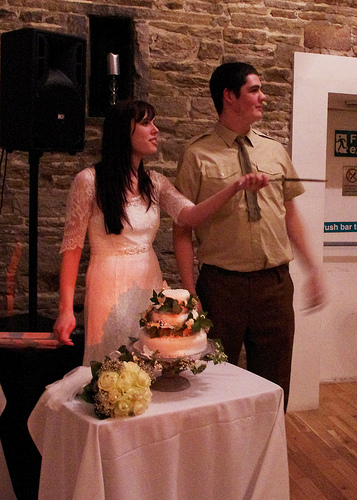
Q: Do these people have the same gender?
A: No, they are both male and female.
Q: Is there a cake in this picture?
A: Yes, there is a cake.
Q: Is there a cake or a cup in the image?
A: Yes, there is a cake.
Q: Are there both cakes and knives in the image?
A: Yes, there are both a cake and a knife.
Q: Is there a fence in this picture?
A: No, there are no fences.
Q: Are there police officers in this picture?
A: No, there are no police officers.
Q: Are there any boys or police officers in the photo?
A: No, there are no police officers or boys.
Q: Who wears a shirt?
A: The man wears a shirt.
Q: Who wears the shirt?
A: The man wears a shirt.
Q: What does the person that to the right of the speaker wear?
A: The man wears a shirt.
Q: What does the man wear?
A: The man wears a shirt.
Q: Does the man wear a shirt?
A: Yes, the man wears a shirt.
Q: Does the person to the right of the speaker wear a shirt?
A: Yes, the man wears a shirt.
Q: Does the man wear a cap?
A: No, the man wears a shirt.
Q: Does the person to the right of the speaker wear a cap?
A: No, the man wears a shirt.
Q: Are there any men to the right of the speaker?
A: Yes, there is a man to the right of the speaker.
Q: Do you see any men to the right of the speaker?
A: Yes, there is a man to the right of the speaker.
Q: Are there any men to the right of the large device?
A: Yes, there is a man to the right of the speaker.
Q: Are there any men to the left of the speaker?
A: No, the man is to the right of the speaker.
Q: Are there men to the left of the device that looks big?
A: No, the man is to the right of the speaker.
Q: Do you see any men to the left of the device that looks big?
A: No, the man is to the right of the speaker.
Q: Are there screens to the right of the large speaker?
A: No, there is a man to the right of the speaker.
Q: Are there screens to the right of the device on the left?
A: No, there is a man to the right of the speaker.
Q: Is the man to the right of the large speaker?
A: Yes, the man is to the right of the speaker.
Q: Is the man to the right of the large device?
A: Yes, the man is to the right of the speaker.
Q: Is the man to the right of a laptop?
A: No, the man is to the right of the speaker.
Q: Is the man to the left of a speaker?
A: No, the man is to the right of a speaker.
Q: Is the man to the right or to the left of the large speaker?
A: The man is to the right of the speaker.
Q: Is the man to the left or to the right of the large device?
A: The man is to the right of the speaker.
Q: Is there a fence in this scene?
A: No, there are no fences.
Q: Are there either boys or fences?
A: No, there are no fences or boys.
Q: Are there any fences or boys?
A: No, there are no fences or boys.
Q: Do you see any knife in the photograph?
A: Yes, there is a knife.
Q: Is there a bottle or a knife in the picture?
A: Yes, there is a knife.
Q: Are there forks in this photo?
A: No, there are no forks.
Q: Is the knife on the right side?
A: Yes, the knife is on the right of the image.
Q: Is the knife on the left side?
A: No, the knife is on the right of the image.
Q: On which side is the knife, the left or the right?
A: The knife is on the right of the image.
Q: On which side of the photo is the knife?
A: The knife is on the right of the image.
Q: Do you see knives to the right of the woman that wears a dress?
A: Yes, there is a knife to the right of the woman.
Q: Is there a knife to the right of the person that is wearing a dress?
A: Yes, there is a knife to the right of the woman.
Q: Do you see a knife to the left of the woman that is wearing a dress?
A: No, the knife is to the right of the woman.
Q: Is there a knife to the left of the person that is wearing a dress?
A: No, the knife is to the right of the woman.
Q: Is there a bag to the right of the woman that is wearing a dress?
A: No, there is a knife to the right of the woman.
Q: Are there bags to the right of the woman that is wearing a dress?
A: No, there is a knife to the right of the woman.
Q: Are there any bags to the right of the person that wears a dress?
A: No, there is a knife to the right of the woman.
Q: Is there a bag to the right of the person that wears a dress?
A: No, there is a knife to the right of the woman.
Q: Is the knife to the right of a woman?
A: Yes, the knife is to the right of a woman.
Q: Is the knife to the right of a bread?
A: No, the knife is to the right of a woman.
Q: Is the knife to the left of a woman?
A: No, the knife is to the right of a woman.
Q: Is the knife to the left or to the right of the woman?
A: The knife is to the right of the woman.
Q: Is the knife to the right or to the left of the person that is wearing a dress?
A: The knife is to the right of the woman.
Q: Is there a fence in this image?
A: No, there are no fences.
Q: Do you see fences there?
A: No, there are no fences.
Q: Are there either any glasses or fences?
A: No, there are no fences or glasses.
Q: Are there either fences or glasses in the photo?
A: No, there are no fences or glasses.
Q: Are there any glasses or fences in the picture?
A: No, there are no fences or glasses.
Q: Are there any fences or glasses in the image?
A: No, there are no fences or glasses.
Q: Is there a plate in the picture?
A: Yes, there is a plate.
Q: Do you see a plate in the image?
A: Yes, there is a plate.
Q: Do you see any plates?
A: Yes, there is a plate.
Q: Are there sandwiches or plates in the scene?
A: Yes, there is a plate.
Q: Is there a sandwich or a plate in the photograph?
A: Yes, there is a plate.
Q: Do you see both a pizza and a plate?
A: No, there is a plate but no pizzas.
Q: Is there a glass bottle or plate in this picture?
A: Yes, there is a glass plate.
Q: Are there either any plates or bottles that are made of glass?
A: Yes, the plate is made of glass.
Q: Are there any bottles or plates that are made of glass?
A: Yes, the plate is made of glass.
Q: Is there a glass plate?
A: Yes, there is a plate that is made of glass.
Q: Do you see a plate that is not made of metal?
A: Yes, there is a plate that is made of glass.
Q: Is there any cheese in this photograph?
A: No, there is no cheese.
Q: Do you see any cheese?
A: No, there is no cheese.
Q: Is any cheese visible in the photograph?
A: No, there is no cheese.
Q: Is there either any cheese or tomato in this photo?
A: No, there are no cheese or tomatoes.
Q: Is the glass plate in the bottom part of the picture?
A: Yes, the plate is in the bottom of the image.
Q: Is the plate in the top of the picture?
A: No, the plate is in the bottom of the image.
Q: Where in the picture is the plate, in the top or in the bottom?
A: The plate is in the bottom of the image.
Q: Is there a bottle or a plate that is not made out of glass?
A: No, there is a plate but it is made of glass.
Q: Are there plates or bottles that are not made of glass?
A: No, there is a plate but it is made of glass.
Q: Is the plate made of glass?
A: Yes, the plate is made of glass.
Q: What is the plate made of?
A: The plate is made of glass.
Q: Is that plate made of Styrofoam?
A: No, the plate is made of glass.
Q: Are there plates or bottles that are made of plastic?
A: No, there is a plate but it is made of glass.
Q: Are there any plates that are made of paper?
A: No, there is a plate but it is made of glass.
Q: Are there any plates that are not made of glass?
A: No, there is a plate but it is made of glass.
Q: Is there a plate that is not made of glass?
A: No, there is a plate but it is made of glass.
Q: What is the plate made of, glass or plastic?
A: The plate is made of glass.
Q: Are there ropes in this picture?
A: No, there are no ropes.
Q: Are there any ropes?
A: No, there are no ropes.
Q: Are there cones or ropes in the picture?
A: No, there are no ropes or cones.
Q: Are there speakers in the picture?
A: Yes, there is a speaker.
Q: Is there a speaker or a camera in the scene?
A: Yes, there is a speaker.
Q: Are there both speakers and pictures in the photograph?
A: No, there is a speaker but no pictures.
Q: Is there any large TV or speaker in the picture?
A: Yes, there is a large speaker.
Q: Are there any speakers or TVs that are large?
A: Yes, the speaker is large.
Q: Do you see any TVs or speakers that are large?
A: Yes, the speaker is large.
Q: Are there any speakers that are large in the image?
A: Yes, there is a large speaker.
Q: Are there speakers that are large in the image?
A: Yes, there is a large speaker.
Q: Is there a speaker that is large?
A: Yes, there is a speaker that is large.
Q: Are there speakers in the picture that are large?
A: Yes, there is a speaker that is large.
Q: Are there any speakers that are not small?
A: Yes, there is a large speaker.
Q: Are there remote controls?
A: No, there are no remote controls.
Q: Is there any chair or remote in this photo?
A: No, there are no remote controls or chairs.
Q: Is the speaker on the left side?
A: Yes, the speaker is on the left of the image.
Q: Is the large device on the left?
A: Yes, the speaker is on the left of the image.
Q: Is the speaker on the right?
A: No, the speaker is on the left of the image.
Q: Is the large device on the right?
A: No, the speaker is on the left of the image.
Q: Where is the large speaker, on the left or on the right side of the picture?
A: The speaker is on the left of the image.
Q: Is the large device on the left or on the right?
A: The speaker is on the left of the image.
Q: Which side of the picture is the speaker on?
A: The speaker is on the left of the image.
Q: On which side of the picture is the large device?
A: The speaker is on the left of the image.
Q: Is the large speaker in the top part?
A: Yes, the speaker is in the top of the image.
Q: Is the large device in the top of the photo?
A: Yes, the speaker is in the top of the image.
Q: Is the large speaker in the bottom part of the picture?
A: No, the speaker is in the top of the image.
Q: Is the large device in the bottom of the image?
A: No, the speaker is in the top of the image.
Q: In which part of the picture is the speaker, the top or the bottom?
A: The speaker is in the top of the image.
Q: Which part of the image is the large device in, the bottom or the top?
A: The speaker is in the top of the image.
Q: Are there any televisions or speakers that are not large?
A: No, there is a speaker but it is large.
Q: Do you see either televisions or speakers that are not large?
A: No, there is a speaker but it is large.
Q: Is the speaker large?
A: Yes, the speaker is large.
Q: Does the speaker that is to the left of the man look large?
A: Yes, the speaker is large.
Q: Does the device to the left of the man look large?
A: Yes, the speaker is large.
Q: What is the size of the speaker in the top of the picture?
A: The speaker is large.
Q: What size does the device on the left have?
A: The speaker has large size.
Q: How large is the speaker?
A: The speaker is large.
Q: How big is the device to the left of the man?
A: The speaker is large.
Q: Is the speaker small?
A: No, the speaker is large.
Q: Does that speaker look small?
A: No, the speaker is large.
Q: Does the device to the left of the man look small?
A: No, the speaker is large.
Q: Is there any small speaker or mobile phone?
A: No, there is a speaker but it is large.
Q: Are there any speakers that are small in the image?
A: No, there is a speaker but it is large.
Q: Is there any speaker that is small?
A: No, there is a speaker but it is large.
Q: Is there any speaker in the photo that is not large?
A: No, there is a speaker but it is large.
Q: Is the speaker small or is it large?
A: The speaker is large.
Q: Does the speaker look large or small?
A: The speaker is large.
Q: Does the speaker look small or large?
A: The speaker is large.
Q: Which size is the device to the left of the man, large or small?
A: The speaker is large.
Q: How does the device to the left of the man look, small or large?
A: The speaker is large.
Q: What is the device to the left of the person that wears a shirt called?
A: The device is a speaker.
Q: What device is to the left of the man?
A: The device is a speaker.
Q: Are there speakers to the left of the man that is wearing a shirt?
A: Yes, there is a speaker to the left of the man.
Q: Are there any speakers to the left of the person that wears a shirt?
A: Yes, there is a speaker to the left of the man.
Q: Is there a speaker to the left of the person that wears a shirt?
A: Yes, there is a speaker to the left of the man.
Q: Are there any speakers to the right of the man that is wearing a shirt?
A: No, the speaker is to the left of the man.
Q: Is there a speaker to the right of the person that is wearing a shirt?
A: No, the speaker is to the left of the man.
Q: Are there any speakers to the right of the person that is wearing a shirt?
A: No, the speaker is to the left of the man.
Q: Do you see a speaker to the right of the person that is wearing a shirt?
A: No, the speaker is to the left of the man.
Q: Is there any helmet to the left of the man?
A: No, there is a speaker to the left of the man.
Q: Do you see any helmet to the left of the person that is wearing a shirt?
A: No, there is a speaker to the left of the man.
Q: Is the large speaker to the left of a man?
A: Yes, the speaker is to the left of a man.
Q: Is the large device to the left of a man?
A: Yes, the speaker is to the left of a man.